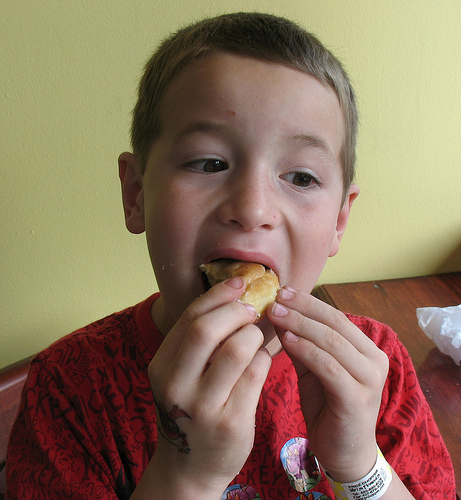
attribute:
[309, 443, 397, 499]
tag — yellow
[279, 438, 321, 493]
sticker — round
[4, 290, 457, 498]
shirt — red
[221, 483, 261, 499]
sticker — round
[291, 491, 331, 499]
sticker — round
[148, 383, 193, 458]
artwork — fake, removeable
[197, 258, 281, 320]
food — delicious, stuffed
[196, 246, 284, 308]
mouth — open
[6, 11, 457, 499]
boy — eating, young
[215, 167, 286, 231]
nose — freckled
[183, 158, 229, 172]
eye — brown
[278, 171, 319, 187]
eye — brown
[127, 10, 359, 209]
hair — brown, short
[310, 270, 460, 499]
table — brown, wood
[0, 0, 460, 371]
wall — yellow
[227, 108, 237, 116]
scratch — small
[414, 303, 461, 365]
bag — white, plastic